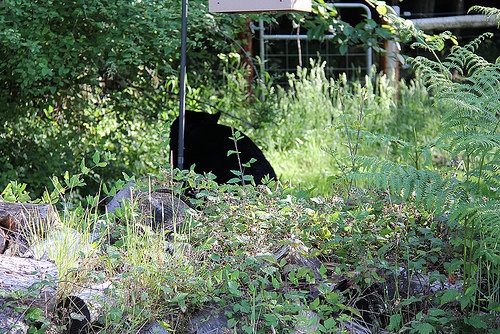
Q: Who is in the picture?
A: A cat.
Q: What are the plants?
A: Flowers.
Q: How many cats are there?
A: One.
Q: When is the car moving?
A: No car.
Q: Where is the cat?
A: In middle.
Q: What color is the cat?
A: Black.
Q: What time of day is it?
A: Day time.